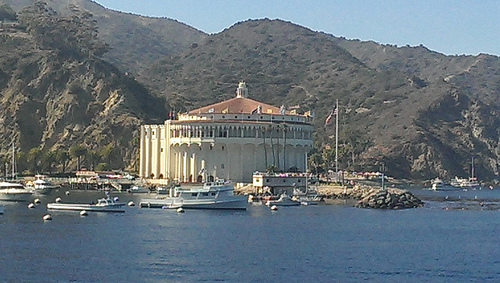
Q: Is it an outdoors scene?
A: Yes, it is outdoors.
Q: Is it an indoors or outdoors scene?
A: It is outdoors.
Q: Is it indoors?
A: No, it is outdoors.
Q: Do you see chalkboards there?
A: No, there are no chalkboards.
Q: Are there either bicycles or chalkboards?
A: No, there are no chalkboards or bicycles.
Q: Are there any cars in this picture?
A: No, there are no cars.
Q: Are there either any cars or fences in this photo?
A: No, there are no cars or fences.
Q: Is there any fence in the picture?
A: No, there are no fences.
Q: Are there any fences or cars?
A: No, there are no fences or cars.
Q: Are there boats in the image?
A: Yes, there is a boat.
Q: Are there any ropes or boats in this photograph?
A: Yes, there is a boat.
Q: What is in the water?
A: The boat is in the water.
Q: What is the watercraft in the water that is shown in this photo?
A: The watercraft is a boat.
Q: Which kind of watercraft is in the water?
A: The watercraft is a boat.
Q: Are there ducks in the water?
A: No, there is a boat in the water.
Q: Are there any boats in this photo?
A: Yes, there is a boat.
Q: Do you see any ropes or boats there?
A: Yes, there is a boat.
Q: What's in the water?
A: The boat is in the water.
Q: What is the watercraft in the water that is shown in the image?
A: The watercraft is a boat.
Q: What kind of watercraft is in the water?
A: The watercraft is a boat.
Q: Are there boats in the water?
A: Yes, there is a boat in the water.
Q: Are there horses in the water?
A: No, there is a boat in the water.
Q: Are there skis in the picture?
A: No, there are no skis.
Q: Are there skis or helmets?
A: No, there are no skis or helmets.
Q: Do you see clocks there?
A: No, there are no clocks.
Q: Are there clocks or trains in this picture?
A: No, there are no clocks or trains.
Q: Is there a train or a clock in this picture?
A: No, there are no clocks or trains.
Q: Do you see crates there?
A: No, there are no crates.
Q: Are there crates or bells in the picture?
A: No, there are no crates or bells.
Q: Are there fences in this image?
A: No, there are no fences.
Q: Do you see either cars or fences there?
A: No, there are no fences or cars.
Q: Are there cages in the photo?
A: No, there are no cages.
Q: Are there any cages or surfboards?
A: No, there are no cages or surfboards.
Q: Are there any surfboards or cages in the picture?
A: No, there are no cages or surfboards.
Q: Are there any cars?
A: No, there are no cars.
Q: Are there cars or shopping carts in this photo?
A: No, there are no cars or shopping carts.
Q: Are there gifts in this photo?
A: No, there are no gifts.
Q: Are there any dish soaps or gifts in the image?
A: No, there are no gifts or dish soaps.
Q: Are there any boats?
A: Yes, there is a boat.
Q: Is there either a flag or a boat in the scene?
A: Yes, there is a boat.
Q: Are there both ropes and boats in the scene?
A: No, there is a boat but no ropes.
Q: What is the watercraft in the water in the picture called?
A: The watercraft is a boat.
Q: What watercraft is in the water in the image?
A: The watercraft is a boat.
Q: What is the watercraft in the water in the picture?
A: The watercraft is a boat.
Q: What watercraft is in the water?
A: The watercraft is a boat.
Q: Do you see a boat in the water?
A: Yes, there is a boat in the water.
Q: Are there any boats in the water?
A: Yes, there is a boat in the water.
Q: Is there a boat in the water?
A: Yes, there is a boat in the water.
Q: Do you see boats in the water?
A: Yes, there is a boat in the water.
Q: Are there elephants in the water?
A: No, there is a boat in the water.